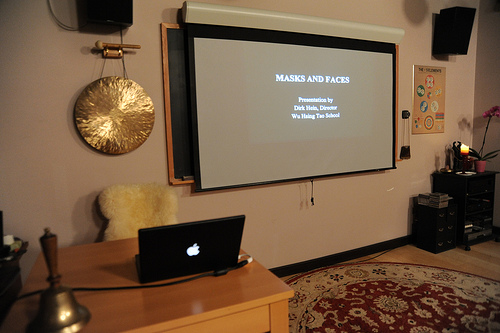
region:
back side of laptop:
[127, 205, 262, 292]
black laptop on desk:
[129, 202, 258, 295]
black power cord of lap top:
[91, 278, 129, 297]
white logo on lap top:
[179, 234, 204, 265]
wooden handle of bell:
[37, 227, 59, 286]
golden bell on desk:
[43, 285, 86, 331]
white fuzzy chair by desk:
[91, 171, 177, 241]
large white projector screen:
[188, 47, 393, 186]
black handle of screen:
[301, 178, 323, 214]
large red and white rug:
[296, 245, 485, 331]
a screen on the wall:
[186, 19, 465, 192]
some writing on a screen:
[250, 57, 366, 181]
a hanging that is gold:
[59, 34, 172, 154]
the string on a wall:
[85, 40, 147, 76]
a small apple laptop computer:
[115, 209, 267, 281]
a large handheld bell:
[14, 224, 86, 331]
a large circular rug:
[265, 233, 462, 330]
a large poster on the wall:
[407, 44, 467, 131]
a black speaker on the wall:
[431, 10, 484, 59]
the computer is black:
[124, 202, 375, 325]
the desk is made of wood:
[120, 290, 221, 323]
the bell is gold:
[13, 225, 86, 323]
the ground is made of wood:
[397, 244, 477, 282]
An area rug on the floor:
[278, 255, 498, 330]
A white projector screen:
[186, 33, 402, 190]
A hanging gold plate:
[68, 44, 157, 158]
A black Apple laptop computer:
[128, 211, 250, 287]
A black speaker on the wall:
[424, 4, 480, 64]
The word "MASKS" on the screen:
[271, 68, 309, 88]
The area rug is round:
[281, 257, 498, 331]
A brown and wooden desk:
[4, 223, 298, 331]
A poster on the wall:
[410, 61, 450, 139]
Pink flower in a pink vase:
[472, 104, 498, 176]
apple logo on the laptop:
[175, 235, 206, 263]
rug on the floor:
[332, 264, 442, 319]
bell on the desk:
[23, 223, 99, 332]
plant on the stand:
[472, 98, 496, 183]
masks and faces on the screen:
[267, 61, 359, 88]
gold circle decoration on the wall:
[54, 63, 169, 166]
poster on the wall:
[409, 56, 450, 140]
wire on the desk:
[102, 278, 130, 298]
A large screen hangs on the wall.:
[169, 10, 404, 190]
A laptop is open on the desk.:
[114, 202, 249, 281]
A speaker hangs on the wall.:
[423, 3, 478, 60]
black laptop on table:
[131, 212, 246, 282]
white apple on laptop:
[186, 242, 203, 259]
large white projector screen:
[191, 32, 397, 188]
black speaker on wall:
[434, 5, 473, 60]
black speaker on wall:
[73, 0, 133, 37]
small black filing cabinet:
[413, 203, 458, 253]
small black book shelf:
[438, 169, 493, 246]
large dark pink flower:
[481, 100, 498, 127]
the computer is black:
[134, 217, 246, 274]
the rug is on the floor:
[290, 261, 488, 331]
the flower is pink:
[480, 98, 499, 123]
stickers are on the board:
[419, 72, 444, 139]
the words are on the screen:
[270, 64, 362, 141]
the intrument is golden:
[79, 73, 155, 175]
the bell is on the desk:
[34, 226, 91, 331]